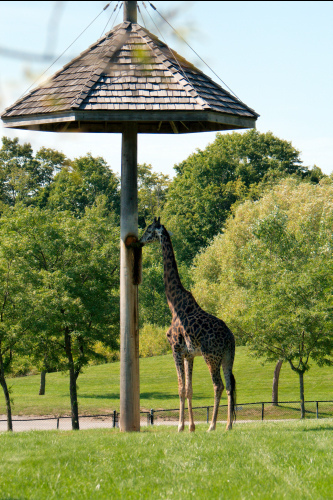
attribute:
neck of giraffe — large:
[151, 243, 200, 301]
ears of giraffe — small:
[149, 216, 170, 228]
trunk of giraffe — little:
[158, 240, 200, 281]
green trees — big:
[195, 134, 287, 195]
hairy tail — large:
[219, 373, 258, 418]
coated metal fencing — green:
[3, 395, 330, 422]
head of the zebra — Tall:
[134, 208, 188, 254]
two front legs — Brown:
[158, 345, 200, 436]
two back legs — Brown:
[196, 354, 260, 442]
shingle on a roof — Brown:
[107, 6, 172, 39]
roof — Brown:
[7, 22, 269, 154]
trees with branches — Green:
[18, 215, 98, 343]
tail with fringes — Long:
[215, 343, 249, 427]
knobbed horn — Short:
[147, 210, 175, 230]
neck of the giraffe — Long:
[153, 230, 187, 304]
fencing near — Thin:
[10, 393, 329, 427]